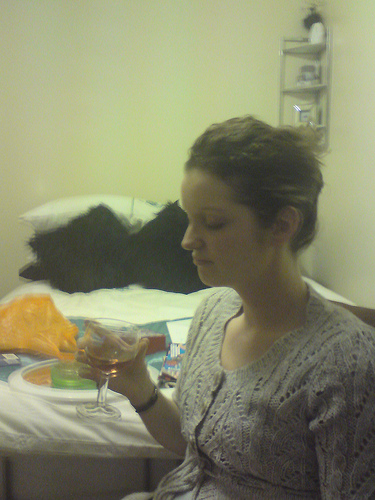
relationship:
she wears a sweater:
[77, 115, 372, 499] [151, 285, 373, 497]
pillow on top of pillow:
[26, 195, 160, 232] [30, 201, 132, 294]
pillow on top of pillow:
[26, 195, 160, 232] [122, 201, 207, 293]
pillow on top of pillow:
[26, 195, 160, 232] [20, 262, 50, 276]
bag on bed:
[2, 293, 79, 362] [1, 280, 215, 498]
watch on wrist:
[133, 383, 160, 412] [120, 371, 165, 419]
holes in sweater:
[278, 375, 312, 407] [151, 285, 373, 497]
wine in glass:
[86, 355, 120, 378] [75, 318, 142, 415]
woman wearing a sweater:
[75, 115, 373, 498] [151, 285, 373, 497]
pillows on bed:
[20, 205, 200, 295] [1, 280, 215, 498]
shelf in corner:
[277, 36, 328, 151] [283, 9, 334, 286]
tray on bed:
[6, 361, 158, 406] [1, 280, 215, 498]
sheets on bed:
[1, 272, 198, 456] [1, 280, 215, 498]